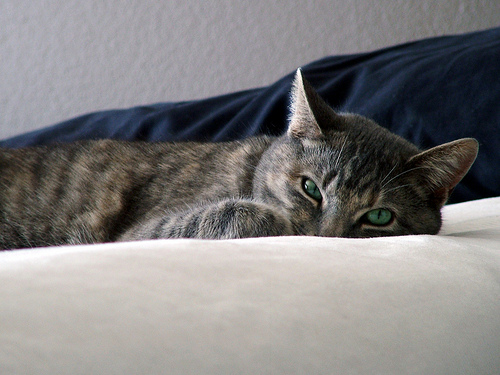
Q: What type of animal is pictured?
A: A cat.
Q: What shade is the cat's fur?
A: Gray and brown.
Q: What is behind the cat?
A: A blue blanket.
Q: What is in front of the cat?
A: A white blanket.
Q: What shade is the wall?
A: White.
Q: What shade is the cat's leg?
A: Gray and brown.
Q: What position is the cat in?
A: Laying on a bed.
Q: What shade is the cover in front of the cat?
A: White.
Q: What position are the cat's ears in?
A: They are up.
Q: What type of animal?
A: Cat.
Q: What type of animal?
A: Cat.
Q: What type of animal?
A: Cat.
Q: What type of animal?
A: Cat.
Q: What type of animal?
A: Cat.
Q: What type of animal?
A: Cat.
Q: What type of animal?
A: Cat.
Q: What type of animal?
A: Cat.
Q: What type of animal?
A: Cat.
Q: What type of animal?
A: Cat.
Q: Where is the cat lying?
A: On a bed.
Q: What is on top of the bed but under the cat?
A: Fuzzy blanket.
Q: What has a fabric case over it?
A: The pillow.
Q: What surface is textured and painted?
A: The wall.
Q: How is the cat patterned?
A: In stripes.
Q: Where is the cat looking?
A: Into the camera.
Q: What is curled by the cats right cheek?
A: A paw.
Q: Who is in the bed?
A: A cat.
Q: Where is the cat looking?
A: In the camera.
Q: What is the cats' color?
A: Grey.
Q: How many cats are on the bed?
A: One.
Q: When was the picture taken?
A: At daytime.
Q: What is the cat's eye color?
A: Green.